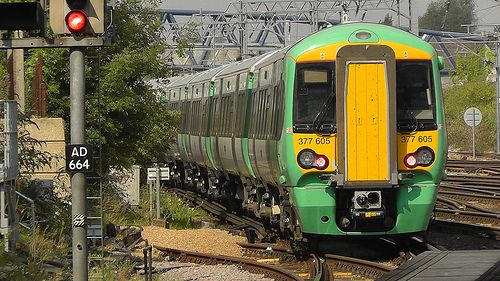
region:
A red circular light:
[63, 8, 90, 35]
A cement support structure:
[12, 111, 72, 209]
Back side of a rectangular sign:
[148, 158, 172, 224]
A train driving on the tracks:
[124, 14, 441, 254]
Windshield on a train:
[293, 59, 438, 131]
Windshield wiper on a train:
[308, 87, 336, 135]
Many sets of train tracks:
[310, 154, 499, 274]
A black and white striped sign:
[71, 213, 87, 228]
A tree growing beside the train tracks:
[12, 0, 199, 227]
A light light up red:
[65, 6, 90, 34]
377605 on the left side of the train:
[292, 133, 333, 146]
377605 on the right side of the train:
[396, 131, 436, 147]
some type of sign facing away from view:
[459, 100, 490, 158]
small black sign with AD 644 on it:
[53, 140, 104, 180]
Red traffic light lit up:
[58, 10, 92, 35]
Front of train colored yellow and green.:
[283, 15, 445, 242]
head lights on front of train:
[296, 145, 438, 170]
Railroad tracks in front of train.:
[305, 244, 436, 271]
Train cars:
[140, 60, 284, 185]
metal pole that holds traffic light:
[39, 42, 104, 278]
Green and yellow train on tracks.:
[197, 21, 456, 255]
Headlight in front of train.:
[292, 142, 333, 175]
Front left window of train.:
[396, 55, 446, 139]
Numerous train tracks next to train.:
[449, 153, 494, 245]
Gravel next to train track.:
[154, 226, 234, 258]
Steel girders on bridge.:
[176, 11, 323, 76]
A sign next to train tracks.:
[461, 98, 488, 162]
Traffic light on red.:
[39, 4, 110, 47]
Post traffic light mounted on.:
[46, 50, 108, 279]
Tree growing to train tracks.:
[27, 6, 179, 171]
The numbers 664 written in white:
[68, 158, 90, 172]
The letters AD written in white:
[67, 145, 90, 158]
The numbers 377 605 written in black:
[295, 134, 333, 147]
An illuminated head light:
[314, 154, 326, 169]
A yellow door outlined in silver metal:
[335, 40, 400, 194]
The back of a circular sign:
[460, 103, 483, 165]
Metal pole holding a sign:
[153, 164, 164, 225]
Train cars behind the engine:
[128, 41, 302, 212]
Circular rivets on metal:
[3, 38, 105, 48]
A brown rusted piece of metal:
[31, 54, 51, 116]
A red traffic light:
[65, 10, 87, 32]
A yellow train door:
[348, 62, 386, 181]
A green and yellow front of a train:
[277, 11, 449, 247]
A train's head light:
[294, 145, 331, 172]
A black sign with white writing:
[64, 142, 92, 173]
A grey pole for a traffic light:
[63, 51, 93, 276]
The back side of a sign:
[460, 105, 487, 158]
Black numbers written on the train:
[296, 133, 333, 148]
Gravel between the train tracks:
[141, 223, 291, 273]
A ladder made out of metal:
[76, 46, 109, 274]